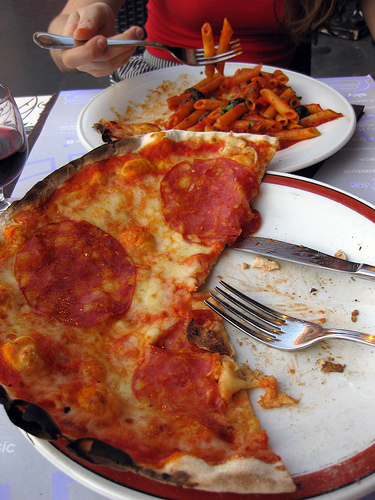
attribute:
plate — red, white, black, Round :
[12, 171, 374, 497]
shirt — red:
[145, 1, 311, 76]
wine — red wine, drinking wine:
[0, 127, 29, 192]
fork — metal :
[186, 264, 374, 383]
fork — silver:
[184, 273, 374, 369]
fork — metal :
[29, 25, 243, 67]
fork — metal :
[24, 19, 248, 75]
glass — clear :
[0, 70, 35, 211]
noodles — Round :
[159, 56, 343, 158]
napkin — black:
[299, 101, 365, 180]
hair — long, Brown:
[262, 3, 337, 37]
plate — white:
[279, 175, 369, 236]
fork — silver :
[32, 30, 241, 66]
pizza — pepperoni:
[4, 147, 304, 497]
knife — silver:
[222, 220, 373, 302]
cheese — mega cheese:
[103, 287, 173, 348]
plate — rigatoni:
[279, 67, 370, 121]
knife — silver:
[225, 230, 372, 292]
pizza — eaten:
[0, 131, 261, 489]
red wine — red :
[2, 124, 30, 191]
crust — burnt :
[2, 385, 307, 499]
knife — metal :
[232, 229, 372, 280]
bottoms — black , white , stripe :
[104, 48, 185, 87]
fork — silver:
[202, 275, 373, 358]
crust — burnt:
[0, 128, 238, 492]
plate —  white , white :
[74, 55, 367, 179]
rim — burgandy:
[276, 447, 359, 493]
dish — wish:
[73, 58, 355, 175]